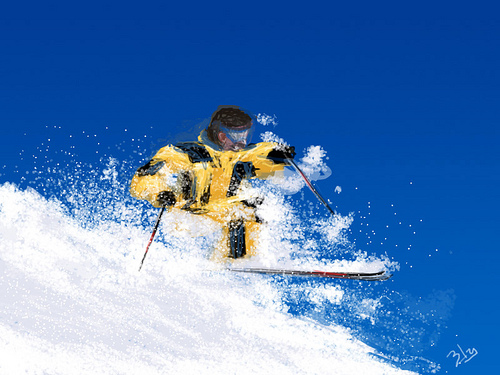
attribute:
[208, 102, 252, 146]
hair — brown 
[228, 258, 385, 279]
skis — black, red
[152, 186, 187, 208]
hand — gloved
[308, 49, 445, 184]
sky — clear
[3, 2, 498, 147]
sky — bright blue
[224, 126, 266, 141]
goggles — blue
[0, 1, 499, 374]
sky — cloudless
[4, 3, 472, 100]
sky — blue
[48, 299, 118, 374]
snow — white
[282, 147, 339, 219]
ski pole — red, black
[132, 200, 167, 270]
ski pole — red, black